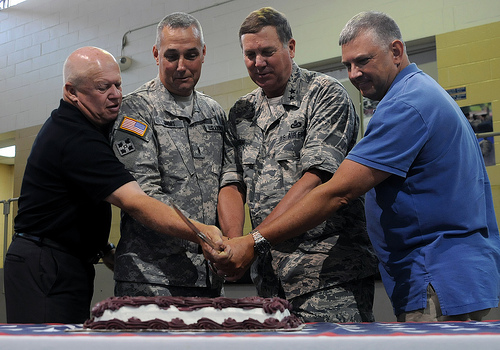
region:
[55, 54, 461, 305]
four men hold knife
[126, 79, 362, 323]
two men wearing camouflage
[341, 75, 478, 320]
man has blue shirt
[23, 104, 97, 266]
man has black shirt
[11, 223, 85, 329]
man has black pants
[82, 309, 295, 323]
white icing on cake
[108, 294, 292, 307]
brown icing on cake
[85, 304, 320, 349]
cake on red white and blue table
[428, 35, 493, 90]
yellow wall behind men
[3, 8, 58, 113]
white wall near ceiling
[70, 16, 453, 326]
four people cutting cake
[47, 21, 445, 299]
four people hold knife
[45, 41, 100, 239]
man has black shirt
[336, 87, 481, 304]
man has blue shirt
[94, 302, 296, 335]
brown icing on cake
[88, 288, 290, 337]
cake on US flag table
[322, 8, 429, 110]
the head of a man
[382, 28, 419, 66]
the ear of a man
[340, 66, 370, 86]
the nose of a man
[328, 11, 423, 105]
the face of a man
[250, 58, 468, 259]
the arm of a man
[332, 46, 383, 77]
the eyes of a man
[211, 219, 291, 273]
the hand of a man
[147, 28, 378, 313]
a man wearing a shirt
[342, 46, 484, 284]
a man with a blue shirt on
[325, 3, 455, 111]
a man with grey hair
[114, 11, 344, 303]
Two men are wearing fatigues.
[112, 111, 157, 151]
A man has a flag sewn on his shirt.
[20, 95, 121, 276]
A man is wearing a black shirt.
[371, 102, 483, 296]
A man is wearing a blue shirt.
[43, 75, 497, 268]
A group of men are cutting a cake.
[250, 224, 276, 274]
A man is wearing a silver watch.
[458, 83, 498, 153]
Pictures are hanging on the wall.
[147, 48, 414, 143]
Three men are smiling.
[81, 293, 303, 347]
A cake is sitting on the table.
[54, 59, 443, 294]
4 men are holding a knife.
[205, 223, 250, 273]
hands holding a knife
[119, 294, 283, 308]
purple swirls on a cake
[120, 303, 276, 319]
white frosting on a cake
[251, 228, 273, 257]
a watch on an arm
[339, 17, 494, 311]
a man wearing blue shirt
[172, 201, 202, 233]
the sharp metal point of a knife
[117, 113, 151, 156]
patches on a sleeve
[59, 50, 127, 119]
a balds head on a body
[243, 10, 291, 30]
brown hair on a head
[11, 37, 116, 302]
a man wearing black pants